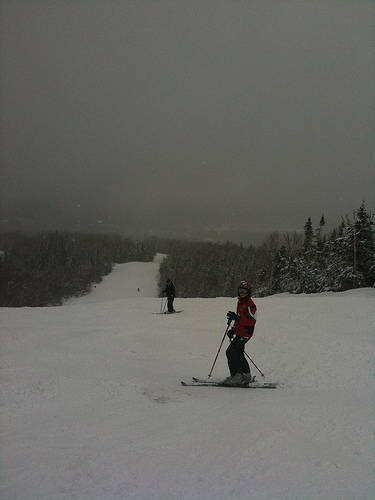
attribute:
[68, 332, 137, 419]
snow — white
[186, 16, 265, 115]
sky — grey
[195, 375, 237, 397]
board — black